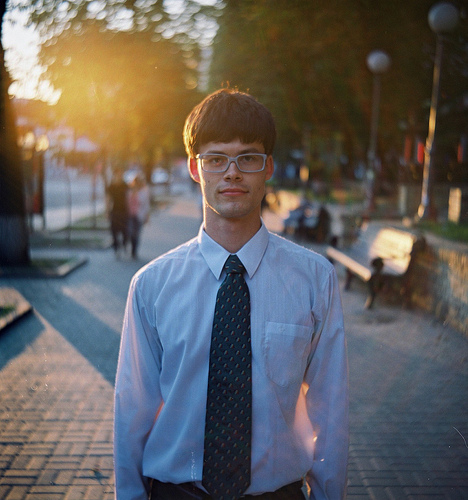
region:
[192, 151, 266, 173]
man wearing glasses with plastic frames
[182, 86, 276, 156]
man has a bowl haircut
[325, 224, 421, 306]
a wooden bench behind the man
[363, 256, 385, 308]
the bench has metal legs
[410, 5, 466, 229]
lampposts behind the man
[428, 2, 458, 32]
the globe on top of lamppost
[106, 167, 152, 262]
a couple walking behind the man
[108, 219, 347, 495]
the man is wearing a white dress shirt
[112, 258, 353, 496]
the mans arms are at his sides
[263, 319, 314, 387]
there is a pocket on the front of the dress shirt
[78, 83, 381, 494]
young man wearing tie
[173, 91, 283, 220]
young man wearing glasses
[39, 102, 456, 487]
young man standing on brick sidewalk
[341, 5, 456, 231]
two streetlamps on grass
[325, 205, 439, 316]
wooden park bench beside wall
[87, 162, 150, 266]
couple walking arm in arm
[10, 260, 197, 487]
shadow of post on sidewalk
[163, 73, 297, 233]
man with short brown hair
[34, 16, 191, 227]
trees beside street curb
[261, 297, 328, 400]
pocket on white shirt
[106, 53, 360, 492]
MAN IN A BLUE TIE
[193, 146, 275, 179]
A PAIR OF GLASSES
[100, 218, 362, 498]
A WHITE DRESS SHIRT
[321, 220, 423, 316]
A WOODEN BENCH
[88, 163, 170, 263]
TWO PEOPLE IN THE BACKGROUND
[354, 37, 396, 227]
A STREET LAMP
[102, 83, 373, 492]
A MAN WEARING GLASSES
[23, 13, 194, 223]
TREES IN THE BACKGROUND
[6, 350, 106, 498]
A BRICK SIDEWALK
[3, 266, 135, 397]
A SHADOW ON THE SIDEWALK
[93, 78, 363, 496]
Young man stand on a street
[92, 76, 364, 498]
Boy wears glasses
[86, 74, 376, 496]
Boy wears a tie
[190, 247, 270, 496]
Tie is blue with small designs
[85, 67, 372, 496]
Boy wears white shirt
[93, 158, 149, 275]
Two persons walking behind boy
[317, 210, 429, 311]
Bench on side street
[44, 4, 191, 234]
Trees on street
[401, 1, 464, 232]
Light pole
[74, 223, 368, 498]
Shirt has long sleeves and a pocket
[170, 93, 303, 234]
a man wearing glasses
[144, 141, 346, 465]
a man in dress clothes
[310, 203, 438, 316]
a park bench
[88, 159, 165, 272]
a couple walking together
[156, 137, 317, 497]
a man wearing a tie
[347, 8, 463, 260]
a couple of street lamps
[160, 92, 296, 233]
man smiling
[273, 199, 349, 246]
a parked car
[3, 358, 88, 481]
sidewalk beside of a road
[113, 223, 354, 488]
a man in a dress shirt